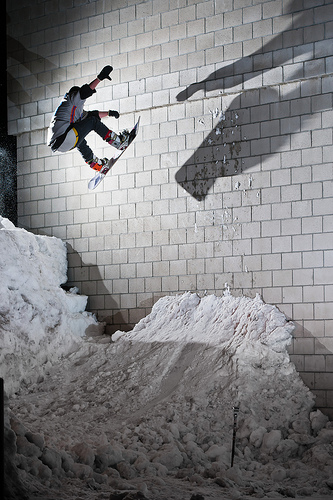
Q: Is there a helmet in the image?
A: No, there are no helmets.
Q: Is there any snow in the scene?
A: Yes, there is snow.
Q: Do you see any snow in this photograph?
A: Yes, there is snow.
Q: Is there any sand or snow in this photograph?
A: Yes, there is snow.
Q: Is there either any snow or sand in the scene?
A: Yes, there is snow.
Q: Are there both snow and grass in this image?
A: No, there is snow but no grass.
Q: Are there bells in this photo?
A: No, there are no bells.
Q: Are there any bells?
A: No, there are no bells.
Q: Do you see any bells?
A: No, there are no bells.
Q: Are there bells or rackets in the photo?
A: No, there are no bells or rackets.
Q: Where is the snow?
A: The snow is on the ground.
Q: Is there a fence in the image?
A: No, there are no fences.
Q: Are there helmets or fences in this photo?
A: No, there are no fences or helmets.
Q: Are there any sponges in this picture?
A: No, there are no sponges.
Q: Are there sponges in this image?
A: No, there are no sponges.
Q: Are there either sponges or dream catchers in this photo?
A: No, there are no sponges or dream catchers.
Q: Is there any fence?
A: No, there are no fences.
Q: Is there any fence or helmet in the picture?
A: No, there are no fences or helmets.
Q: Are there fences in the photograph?
A: No, there are no fences.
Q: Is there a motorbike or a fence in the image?
A: No, there are no fences or motorcycles.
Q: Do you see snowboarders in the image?
A: Yes, there is a snowboarder.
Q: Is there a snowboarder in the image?
A: Yes, there is a snowboarder.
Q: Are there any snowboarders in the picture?
A: Yes, there is a snowboarder.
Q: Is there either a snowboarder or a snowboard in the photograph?
A: Yes, there is a snowboarder.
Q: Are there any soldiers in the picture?
A: No, there are no soldiers.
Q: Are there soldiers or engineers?
A: No, there are no soldiers or engineers.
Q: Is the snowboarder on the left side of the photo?
A: Yes, the snowboarder is on the left of the image.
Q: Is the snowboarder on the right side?
A: No, the snowboarder is on the left of the image.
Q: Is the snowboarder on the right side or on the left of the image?
A: The snowboarder is on the left of the image.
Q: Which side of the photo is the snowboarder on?
A: The snowboarder is on the left of the image.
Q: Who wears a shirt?
A: The snowboarder wears a shirt.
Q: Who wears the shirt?
A: The snowboarder wears a shirt.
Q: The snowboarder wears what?
A: The snowboarder wears a shirt.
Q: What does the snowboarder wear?
A: The snowboarder wears a shirt.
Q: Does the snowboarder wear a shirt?
A: Yes, the snowboarder wears a shirt.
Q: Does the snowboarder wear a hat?
A: No, the snowboarder wears a shirt.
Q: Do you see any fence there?
A: No, there are no fences.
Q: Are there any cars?
A: No, there are no cars.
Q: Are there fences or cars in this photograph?
A: No, there are no cars or fences.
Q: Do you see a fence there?
A: No, there are no fences.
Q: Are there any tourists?
A: No, there are no tourists.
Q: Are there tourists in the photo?
A: No, there are no tourists.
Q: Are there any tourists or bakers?
A: No, there are no tourists or bakers.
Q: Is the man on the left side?
A: Yes, the man is on the left of the image.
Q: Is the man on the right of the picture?
A: No, the man is on the left of the image.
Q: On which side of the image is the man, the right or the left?
A: The man is on the left of the image.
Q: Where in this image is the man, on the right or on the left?
A: The man is on the left of the image.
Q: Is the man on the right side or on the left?
A: The man is on the left of the image.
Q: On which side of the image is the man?
A: The man is on the left of the image.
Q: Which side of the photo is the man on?
A: The man is on the left of the image.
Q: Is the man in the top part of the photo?
A: Yes, the man is in the top of the image.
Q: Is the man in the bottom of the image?
A: No, the man is in the top of the image.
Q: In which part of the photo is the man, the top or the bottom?
A: The man is in the top of the image.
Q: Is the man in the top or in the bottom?
A: The man is in the top of the image.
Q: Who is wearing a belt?
A: The man is wearing a belt.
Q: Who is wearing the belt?
A: The man is wearing a belt.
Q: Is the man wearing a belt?
A: Yes, the man is wearing a belt.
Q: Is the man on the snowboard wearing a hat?
A: No, the man is wearing a belt.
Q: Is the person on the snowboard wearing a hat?
A: No, the man is wearing a belt.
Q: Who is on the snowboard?
A: The man is on the snowboard.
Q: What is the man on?
A: The man is on the snowboard.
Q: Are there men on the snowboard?
A: Yes, there is a man on the snowboard.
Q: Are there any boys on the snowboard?
A: No, there is a man on the snowboard.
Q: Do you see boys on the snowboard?
A: No, there is a man on the snowboard.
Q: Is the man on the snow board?
A: Yes, the man is on the snow board.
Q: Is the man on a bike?
A: No, the man is on the snow board.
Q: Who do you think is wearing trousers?
A: The man is wearing trousers.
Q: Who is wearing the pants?
A: The man is wearing trousers.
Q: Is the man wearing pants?
A: Yes, the man is wearing pants.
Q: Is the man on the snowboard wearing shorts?
A: No, the man is wearing pants.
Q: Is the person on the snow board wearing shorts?
A: No, the man is wearing pants.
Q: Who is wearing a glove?
A: The man is wearing a glove.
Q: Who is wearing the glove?
A: The man is wearing a glove.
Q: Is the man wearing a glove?
A: Yes, the man is wearing a glove.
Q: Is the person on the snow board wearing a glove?
A: Yes, the man is wearing a glove.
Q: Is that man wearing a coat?
A: No, the man is wearing a glove.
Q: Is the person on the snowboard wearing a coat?
A: No, the man is wearing a glove.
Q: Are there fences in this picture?
A: No, there are no fences.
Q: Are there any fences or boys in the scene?
A: No, there are no fences or boys.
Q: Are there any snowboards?
A: Yes, there is a snowboard.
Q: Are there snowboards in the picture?
A: Yes, there is a snowboard.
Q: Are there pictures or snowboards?
A: Yes, there is a snowboard.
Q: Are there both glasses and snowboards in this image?
A: No, there is a snowboard but no glasses.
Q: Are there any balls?
A: No, there are no balls.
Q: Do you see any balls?
A: No, there are no balls.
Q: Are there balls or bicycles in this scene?
A: No, there are no balls or bicycles.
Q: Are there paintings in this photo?
A: No, there are no paintings.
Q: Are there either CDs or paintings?
A: No, there are no paintings or cds.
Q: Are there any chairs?
A: No, there are no chairs.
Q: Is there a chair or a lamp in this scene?
A: No, there are no chairs or lamps.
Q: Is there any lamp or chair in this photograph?
A: No, there are no chairs or lamps.